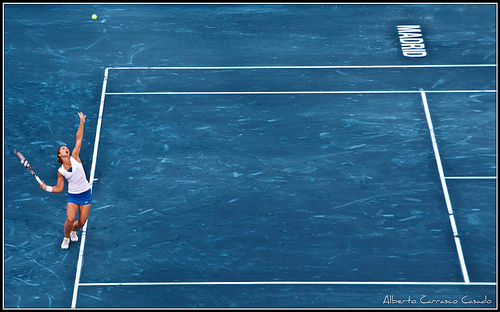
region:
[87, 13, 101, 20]
a small green tennis ball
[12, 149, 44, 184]
a large tennis racket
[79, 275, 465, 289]
a long white line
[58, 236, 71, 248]
a woman's tennis shoe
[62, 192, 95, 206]
a woman's blue skirt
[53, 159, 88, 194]
a woman's white tank top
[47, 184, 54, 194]
a white wristband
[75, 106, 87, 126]
the hand of a woman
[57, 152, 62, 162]
part of a woman's hair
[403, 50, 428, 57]
a white capital letter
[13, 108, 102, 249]
a woman on a tennis court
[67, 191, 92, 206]
a pair of blue shorts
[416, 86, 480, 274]
a white line on a court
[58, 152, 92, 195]
a white tank top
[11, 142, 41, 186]
a tennis racket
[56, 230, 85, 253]
a pair of white tennis shoes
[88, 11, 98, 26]
a green tennis ball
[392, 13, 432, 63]
writting on a tennis court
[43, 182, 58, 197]
a white sweat band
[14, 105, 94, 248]
a tennis player preparing to serve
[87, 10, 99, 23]
a tennis ball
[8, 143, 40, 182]
a tennis racquet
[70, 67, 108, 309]
the white baseline of a tennis court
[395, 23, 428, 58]
the name of a city in large white letters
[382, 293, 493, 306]
a person's name in white script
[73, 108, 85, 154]
a fully outstretched arm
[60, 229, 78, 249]
a pair of white tennis shoes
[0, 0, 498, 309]
a tennis court with a blue surface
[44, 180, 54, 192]
a white wristband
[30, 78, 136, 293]
This is a woman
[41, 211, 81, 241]
These are tennis shoes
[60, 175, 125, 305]
The shorts are dark blue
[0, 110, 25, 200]
This is a tennis racket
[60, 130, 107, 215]
The shirt is white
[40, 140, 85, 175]
This is a head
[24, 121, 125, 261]
This is a tennis player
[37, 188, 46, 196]
This is a sweatband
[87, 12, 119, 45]
This is a tennis ball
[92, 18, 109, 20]
The ball is green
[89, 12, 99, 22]
A tennis ball in the air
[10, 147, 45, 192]
a tennis racket in a womans hand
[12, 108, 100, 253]
a woman serving a tennis ball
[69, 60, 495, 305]
a blue tennis court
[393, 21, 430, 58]
writing on a tennis court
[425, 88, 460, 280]
lines on a tennis court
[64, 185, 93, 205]
blue athletic shorts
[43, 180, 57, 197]
a white wrist band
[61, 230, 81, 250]
a pair of white sneakers